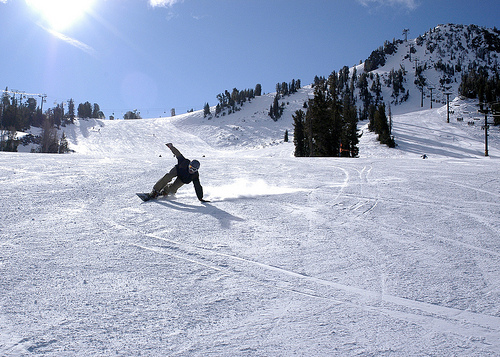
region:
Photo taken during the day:
[11, 2, 489, 347]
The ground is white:
[15, 120, 492, 350]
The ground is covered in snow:
[20, 105, 491, 350]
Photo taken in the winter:
[12, 15, 482, 345]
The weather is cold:
[16, 6, 491, 346]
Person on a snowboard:
[125, 140, 225, 210]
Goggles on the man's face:
[185, 160, 196, 171]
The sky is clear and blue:
[15, 10, 485, 108]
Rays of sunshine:
[15, 0, 150, 87]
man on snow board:
[131, 116, 215, 224]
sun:
[31, 6, 85, 37]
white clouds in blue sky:
[227, 28, 258, 62]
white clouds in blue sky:
[181, 22, 235, 77]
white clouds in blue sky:
[127, 36, 211, 104]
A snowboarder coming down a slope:
[124, 137, 218, 220]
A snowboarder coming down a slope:
[131, 134, 217, 221]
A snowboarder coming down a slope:
[127, 135, 220, 213]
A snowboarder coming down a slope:
[128, 133, 226, 221]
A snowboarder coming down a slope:
[130, 133, 215, 213]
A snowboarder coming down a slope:
[133, 138, 217, 215]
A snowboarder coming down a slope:
[132, 134, 218, 217]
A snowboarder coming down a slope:
[128, 138, 220, 219]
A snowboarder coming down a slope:
[128, 138, 216, 213]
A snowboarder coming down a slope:
[135, 140, 227, 216]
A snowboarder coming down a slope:
[126, 130, 220, 215]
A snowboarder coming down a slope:
[133, 140, 228, 210]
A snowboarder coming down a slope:
[133, 138, 223, 215]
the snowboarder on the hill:
[137, 132, 212, 207]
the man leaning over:
[153, 134, 211, 204]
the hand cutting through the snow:
[206, 178, 286, 200]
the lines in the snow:
[297, 159, 498, 354]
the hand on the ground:
[192, 178, 214, 210]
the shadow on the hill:
[164, 200, 246, 234]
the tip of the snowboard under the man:
[131, 188, 151, 203]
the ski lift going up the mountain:
[395, 25, 498, 153]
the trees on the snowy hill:
[281, 65, 402, 162]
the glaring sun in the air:
[23, 2, 100, 43]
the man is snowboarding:
[23, 51, 395, 355]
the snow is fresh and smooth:
[64, 108, 365, 323]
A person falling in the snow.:
[127, 137, 235, 222]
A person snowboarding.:
[133, 138, 216, 209]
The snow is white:
[27, 213, 459, 338]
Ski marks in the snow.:
[116, 216, 448, 343]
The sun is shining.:
[16, 0, 105, 45]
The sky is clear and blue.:
[23, 15, 335, 90]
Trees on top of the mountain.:
[413, 21, 471, 69]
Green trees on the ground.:
[284, 71, 364, 159]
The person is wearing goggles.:
[188, 162, 203, 169]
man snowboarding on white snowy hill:
[120, 131, 216, 211]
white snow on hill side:
[65, 236, 128, 281]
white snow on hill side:
[353, 275, 390, 308]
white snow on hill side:
[389, 190, 427, 212]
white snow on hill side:
[25, 205, 95, 251]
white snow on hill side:
[328, 325, 364, 342]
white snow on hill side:
[386, 242, 422, 276]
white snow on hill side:
[283, 196, 315, 221]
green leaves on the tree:
[328, 110, 338, 132]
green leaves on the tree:
[316, 98, 343, 141]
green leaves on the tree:
[379, 93, 400, 148]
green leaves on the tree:
[298, 101, 330, 166]